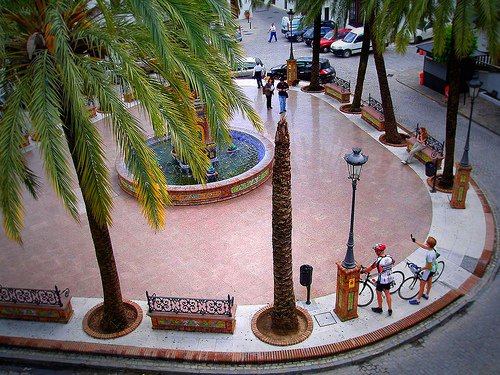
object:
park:
[279, 13, 389, 59]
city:
[0, 0, 500, 375]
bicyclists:
[404, 233, 439, 306]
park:
[344, 233, 447, 316]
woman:
[402, 126, 428, 169]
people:
[262, 77, 276, 111]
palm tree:
[0, 0, 263, 334]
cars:
[328, 27, 391, 59]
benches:
[0, 282, 73, 324]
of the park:
[0, 282, 76, 326]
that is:
[399, 0, 499, 190]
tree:
[414, 0, 500, 190]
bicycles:
[396, 254, 446, 300]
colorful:
[104, 96, 173, 233]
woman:
[398, 124, 429, 168]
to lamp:
[333, 143, 371, 322]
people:
[275, 77, 289, 114]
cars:
[309, 27, 358, 52]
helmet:
[374, 243, 388, 257]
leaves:
[40, 35, 76, 62]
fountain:
[115, 62, 278, 207]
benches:
[404, 123, 443, 169]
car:
[268, 56, 337, 84]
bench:
[144, 290, 236, 335]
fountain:
[144, 289, 238, 335]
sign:
[347, 277, 356, 289]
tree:
[274, 271, 358, 334]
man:
[265, 19, 281, 46]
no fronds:
[262, 107, 301, 337]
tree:
[259, 104, 300, 335]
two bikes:
[353, 232, 442, 317]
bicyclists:
[358, 242, 395, 318]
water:
[222, 136, 245, 161]